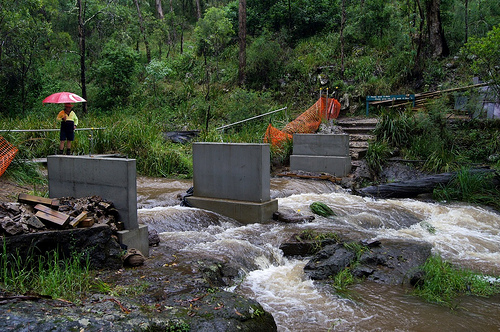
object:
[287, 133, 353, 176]
support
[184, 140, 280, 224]
support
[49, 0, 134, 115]
leaves trees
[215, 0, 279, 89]
leaves trees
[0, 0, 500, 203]
vegetation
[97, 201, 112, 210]
debris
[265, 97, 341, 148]
fence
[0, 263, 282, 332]
flat rock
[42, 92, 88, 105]
umbrella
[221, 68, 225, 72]
leaves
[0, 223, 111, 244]
board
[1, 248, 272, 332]
ground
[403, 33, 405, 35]
leave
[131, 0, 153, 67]
tree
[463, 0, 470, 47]
tree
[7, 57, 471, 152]
bush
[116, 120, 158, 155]
plant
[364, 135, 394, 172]
plant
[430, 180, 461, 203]
plant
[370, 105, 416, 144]
plant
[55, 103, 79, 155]
person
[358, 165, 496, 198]
log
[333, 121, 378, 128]
steps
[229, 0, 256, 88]
trees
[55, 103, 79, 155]
woman looking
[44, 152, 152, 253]
from platform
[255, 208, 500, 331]
grass/water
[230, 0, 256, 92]
tree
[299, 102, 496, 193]
ground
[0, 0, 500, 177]
slope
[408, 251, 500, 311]
grass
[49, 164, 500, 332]
water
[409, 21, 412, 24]
leaves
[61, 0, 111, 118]
trees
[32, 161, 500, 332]
stream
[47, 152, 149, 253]
support